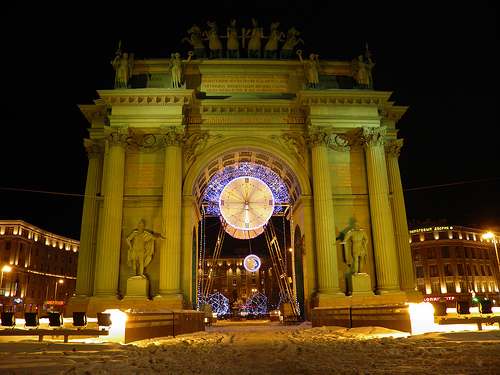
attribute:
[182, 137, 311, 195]
arch — stone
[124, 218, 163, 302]
statue — roman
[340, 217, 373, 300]
statue — roman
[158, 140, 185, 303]
column — roman, stone, large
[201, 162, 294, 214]
lights — purple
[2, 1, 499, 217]
sky — black, dark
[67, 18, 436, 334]
building — large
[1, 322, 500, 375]
walkway — sand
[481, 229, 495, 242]
light — yellow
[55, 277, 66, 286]
light — on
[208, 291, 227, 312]
lights — purple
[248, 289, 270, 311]
lights — purple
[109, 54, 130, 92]
goddess — roman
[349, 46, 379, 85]
goddess — roman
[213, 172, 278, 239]
clock — golden, large, round, lit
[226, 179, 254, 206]
hands — yellow